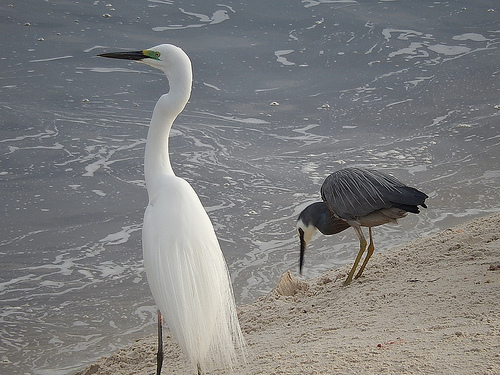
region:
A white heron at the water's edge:
[92, 34, 269, 359]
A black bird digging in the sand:
[285, 160, 425, 305]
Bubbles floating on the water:
[381, 25, 471, 60]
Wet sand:
[276, 300, 411, 361]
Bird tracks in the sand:
[285, 305, 350, 345]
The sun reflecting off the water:
[260, 140, 330, 175]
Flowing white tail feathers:
[131, 235, 281, 356]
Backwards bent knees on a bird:
[332, 207, 382, 287]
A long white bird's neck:
[128, 41, 204, 226]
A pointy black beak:
[97, 44, 143, 63]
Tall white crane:
[86, 29, 264, 371]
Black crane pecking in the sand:
[283, 161, 435, 311]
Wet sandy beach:
[310, 296, 437, 361]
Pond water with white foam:
[250, 19, 472, 116]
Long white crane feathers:
[145, 287, 263, 373]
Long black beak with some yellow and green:
[83, 31, 208, 93]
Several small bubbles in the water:
[18, 6, 130, 47]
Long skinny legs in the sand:
[335, 223, 387, 307]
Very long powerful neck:
[92, 38, 220, 192]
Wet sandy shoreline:
[51, 319, 151, 369]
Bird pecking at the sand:
[286, 150, 432, 297]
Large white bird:
[87, 24, 271, 372]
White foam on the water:
[3, 2, 498, 259]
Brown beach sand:
[89, 222, 499, 373]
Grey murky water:
[8, 5, 472, 146]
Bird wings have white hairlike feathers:
[136, 243, 268, 373]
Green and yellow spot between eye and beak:
[138, 45, 163, 72]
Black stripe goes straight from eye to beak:
[296, 224, 311, 279]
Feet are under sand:
[326, 268, 373, 295]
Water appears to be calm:
[4, 2, 494, 173]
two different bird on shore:
[87, 38, 454, 360]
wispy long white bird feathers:
[162, 233, 252, 369]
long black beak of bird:
[95, 34, 160, 78]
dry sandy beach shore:
[325, 298, 425, 365]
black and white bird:
[291, 152, 431, 307]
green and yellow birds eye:
[137, 41, 171, 78]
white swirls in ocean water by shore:
[380, 13, 478, 85]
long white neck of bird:
[137, 33, 201, 234]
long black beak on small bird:
[293, 220, 313, 284]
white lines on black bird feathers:
[330, 155, 405, 211]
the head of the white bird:
[93, 37, 207, 77]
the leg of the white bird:
[146, 303, 188, 373]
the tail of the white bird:
[160, 273, 245, 369]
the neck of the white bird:
[126, 71, 197, 196]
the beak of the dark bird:
[288, 235, 305, 276]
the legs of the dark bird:
[338, 222, 388, 289]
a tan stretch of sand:
[58, 208, 499, 373]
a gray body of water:
[3, 0, 498, 372]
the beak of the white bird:
[96, 45, 146, 65]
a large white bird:
[97, 39, 269, 374]